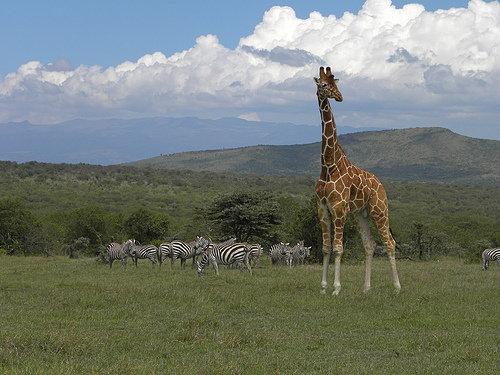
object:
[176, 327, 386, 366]
grass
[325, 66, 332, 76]
horns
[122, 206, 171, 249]
tree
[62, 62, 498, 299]
animals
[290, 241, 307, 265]
zebra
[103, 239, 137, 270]
zebra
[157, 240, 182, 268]
zebra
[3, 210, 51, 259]
tree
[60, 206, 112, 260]
tree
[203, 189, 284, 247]
tree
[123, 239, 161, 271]
zebra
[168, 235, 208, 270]
zebra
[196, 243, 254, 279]
zebra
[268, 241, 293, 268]
zebra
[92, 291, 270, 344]
grass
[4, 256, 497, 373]
ground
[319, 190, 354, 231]
ground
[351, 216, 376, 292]
leg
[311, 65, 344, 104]
head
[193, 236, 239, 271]
zebra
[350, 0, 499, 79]
clouds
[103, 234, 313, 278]
zebra group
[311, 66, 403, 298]
giraffe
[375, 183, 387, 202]
giraffe's spot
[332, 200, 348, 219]
giraffe's spot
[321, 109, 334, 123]
giraffe's spot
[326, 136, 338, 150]
giraffe's spot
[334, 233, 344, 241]
giraffe's spot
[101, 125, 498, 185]
mountain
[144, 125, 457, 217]
hillside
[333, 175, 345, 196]
brown spots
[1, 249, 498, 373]
field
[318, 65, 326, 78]
horns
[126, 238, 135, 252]
head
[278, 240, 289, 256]
head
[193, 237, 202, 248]
head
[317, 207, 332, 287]
leg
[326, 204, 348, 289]
leg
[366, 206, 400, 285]
leg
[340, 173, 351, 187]
spot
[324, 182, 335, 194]
spot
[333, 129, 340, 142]
spot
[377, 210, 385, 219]
spot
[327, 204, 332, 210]
spot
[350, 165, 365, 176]
spots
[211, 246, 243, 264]
stripes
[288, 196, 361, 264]
trees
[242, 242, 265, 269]
zebras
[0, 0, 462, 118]
sky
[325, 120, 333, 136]
spot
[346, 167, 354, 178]
spot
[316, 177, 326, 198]
spot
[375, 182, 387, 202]
spot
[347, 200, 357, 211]
spot